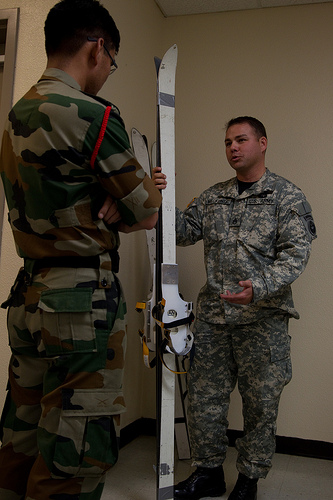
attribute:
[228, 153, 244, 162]
mouth — slightly open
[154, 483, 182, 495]
stripe — silver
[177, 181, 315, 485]
uniform — military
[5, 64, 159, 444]
uniform — military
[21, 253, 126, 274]
belt — black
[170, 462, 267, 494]
boots — black, pair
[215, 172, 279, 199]
collar — open, camouflage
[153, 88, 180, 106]
tape — duct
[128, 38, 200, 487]
skis — vertical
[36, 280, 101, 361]
pocket — back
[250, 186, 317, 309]
sleeve — shirt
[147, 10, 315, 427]
wall — painted, biege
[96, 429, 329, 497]
floor — white, tile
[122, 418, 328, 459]
floor base — black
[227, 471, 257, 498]
man's boot — black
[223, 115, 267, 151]
man's hair — short, black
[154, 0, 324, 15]
ceiling — white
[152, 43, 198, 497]
ski — long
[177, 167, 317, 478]
suit — camouflage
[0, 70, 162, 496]
suit — camouflage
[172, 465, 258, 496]
boots — black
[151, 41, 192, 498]
skis — white, gray